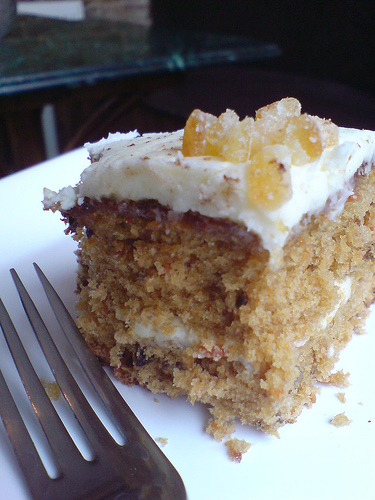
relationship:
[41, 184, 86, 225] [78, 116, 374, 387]
piece of cake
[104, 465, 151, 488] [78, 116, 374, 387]
silver fork next to cake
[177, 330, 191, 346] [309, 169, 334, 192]
thin layer of frosting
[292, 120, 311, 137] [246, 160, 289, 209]
yellow sugar cake topping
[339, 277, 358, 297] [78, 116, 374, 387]
midlayer frosting on cake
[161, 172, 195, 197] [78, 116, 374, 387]
white cake frosting on cake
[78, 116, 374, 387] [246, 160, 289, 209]
cake with yellow topping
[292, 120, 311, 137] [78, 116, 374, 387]
yellow and brown cake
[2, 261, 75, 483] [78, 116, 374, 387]
fork next to cake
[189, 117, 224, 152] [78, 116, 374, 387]
fruit on cake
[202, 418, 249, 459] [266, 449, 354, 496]
crumbs on plate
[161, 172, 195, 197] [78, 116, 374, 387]
white frosting between cake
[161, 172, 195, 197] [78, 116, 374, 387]
white frosting on cake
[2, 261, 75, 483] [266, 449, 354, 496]
fork on plate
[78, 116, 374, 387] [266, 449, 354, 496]
cake on plate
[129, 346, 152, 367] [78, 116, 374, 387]
raisins in cake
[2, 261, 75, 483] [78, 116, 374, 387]
fork besides cake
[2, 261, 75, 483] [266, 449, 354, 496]
fork near plate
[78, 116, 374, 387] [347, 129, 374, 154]
cake has cream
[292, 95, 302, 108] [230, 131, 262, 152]
edge of a potato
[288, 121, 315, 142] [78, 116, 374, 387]
crunch of a cake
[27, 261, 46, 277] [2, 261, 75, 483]
edge of a fork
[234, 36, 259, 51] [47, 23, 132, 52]
part of a table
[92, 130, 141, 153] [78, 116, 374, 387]
edge of cake